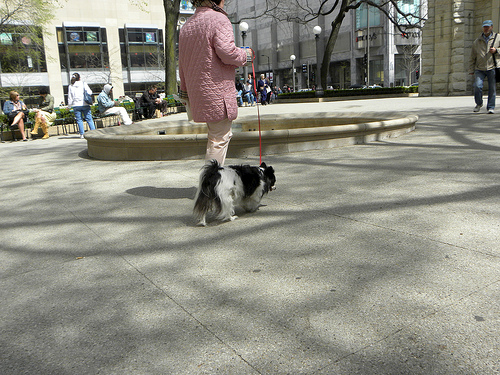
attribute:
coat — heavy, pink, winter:
[174, 0, 250, 125]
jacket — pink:
[181, 15, 246, 125]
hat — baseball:
[483, 17, 492, 27]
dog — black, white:
[202, 151, 345, 211]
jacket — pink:
[168, 10, 258, 123]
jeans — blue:
[66, 104, 95, 135]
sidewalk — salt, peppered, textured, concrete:
[12, 228, 493, 373]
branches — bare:
[271, 2, 334, 23]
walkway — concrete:
[1, 99, 498, 374]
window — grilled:
[58, 24, 126, 84]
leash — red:
[251, 46, 266, 167]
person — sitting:
[94, 82, 131, 126]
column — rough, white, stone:
[449, 4, 478, 93]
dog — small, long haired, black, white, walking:
[188, 155, 281, 225]